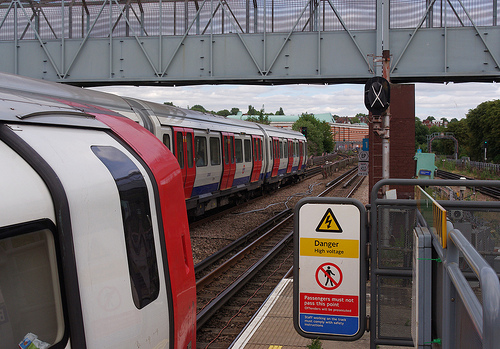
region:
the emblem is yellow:
[316, 208, 343, 235]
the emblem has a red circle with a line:
[315, 259, 343, 291]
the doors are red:
[224, 134, 236, 188]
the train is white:
[58, 158, 101, 217]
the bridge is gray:
[281, 44, 319, 67]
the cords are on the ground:
[293, 182, 316, 199]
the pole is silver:
[380, 149, 392, 174]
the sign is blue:
[360, 137, 371, 153]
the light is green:
[479, 136, 489, 148]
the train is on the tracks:
[198, 201, 233, 220]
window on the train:
[207, 137, 224, 167]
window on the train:
[233, 143, 243, 170]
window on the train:
[239, 140, 252, 170]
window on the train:
[248, 140, 260, 156]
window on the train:
[263, 143, 279, 165]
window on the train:
[106, 178, 169, 319]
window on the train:
[268, 141, 276, 163]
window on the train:
[280, 140, 291, 159]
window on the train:
[283, 144, 293, 160]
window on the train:
[189, 133, 208, 167]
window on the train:
[256, 143, 263, 159]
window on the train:
[1, 231, 63, 347]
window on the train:
[289, 142, 300, 154]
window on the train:
[273, 143, 281, 163]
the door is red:
[168, 118, 210, 202]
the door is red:
[207, 128, 253, 226]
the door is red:
[152, 111, 214, 236]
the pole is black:
[358, 168, 406, 336]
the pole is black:
[337, 165, 382, 346]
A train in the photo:
[130, 101, 236, 174]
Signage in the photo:
[285, 197, 369, 347]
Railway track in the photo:
[208, 222, 271, 319]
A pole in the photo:
[372, 124, 417, 175]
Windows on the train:
[194, 142, 228, 167]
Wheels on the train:
[201, 199, 260, 218]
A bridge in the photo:
[251, 18, 369, 61]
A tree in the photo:
[287, 113, 337, 144]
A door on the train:
[219, 142, 235, 194]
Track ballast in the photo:
[214, 230, 264, 295]